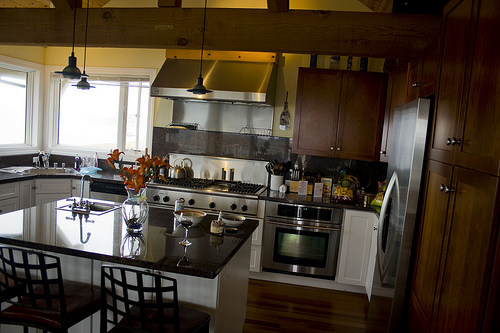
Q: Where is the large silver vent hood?
A: Above stove.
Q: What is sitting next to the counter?
A: Two bar stools.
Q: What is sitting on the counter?
A: A vase with flowers.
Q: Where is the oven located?
A: Under the counter?.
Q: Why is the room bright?
A: It is daytime.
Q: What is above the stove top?
A: A silver hood.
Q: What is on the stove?
A: A teapot.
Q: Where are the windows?
A: The corner.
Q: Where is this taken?
A: A kitchen.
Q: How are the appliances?
A: Stainless steel.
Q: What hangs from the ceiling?
A: Light fixtures.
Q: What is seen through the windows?
A: Day light.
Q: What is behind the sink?
A: Windows.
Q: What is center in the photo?
A: A kitchen island.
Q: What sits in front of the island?
A: Chairs.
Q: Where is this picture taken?
A: A kitchen.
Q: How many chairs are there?
A: Two.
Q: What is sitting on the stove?
A: A tea kettle.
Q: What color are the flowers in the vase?
A: Orange.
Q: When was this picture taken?
A: During the day.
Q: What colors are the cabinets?
A: Brown and white.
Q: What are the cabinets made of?
A: Wood.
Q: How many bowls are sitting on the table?
A: Two.